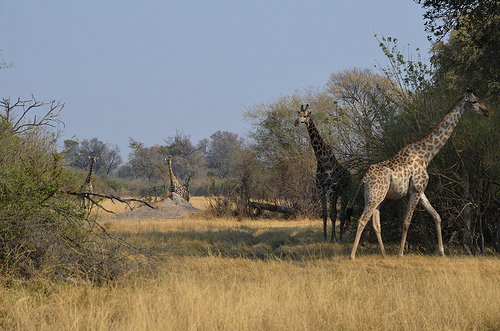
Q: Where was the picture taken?
A: It was taken at the forest.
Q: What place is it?
A: It is a forest.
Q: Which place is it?
A: It is a forest.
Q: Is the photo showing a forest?
A: Yes, it is showing a forest.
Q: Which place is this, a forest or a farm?
A: It is a forest.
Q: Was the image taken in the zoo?
A: No, the picture was taken in the forest.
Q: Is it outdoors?
A: Yes, it is outdoors.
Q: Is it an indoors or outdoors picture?
A: It is outdoors.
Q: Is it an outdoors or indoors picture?
A: It is outdoors.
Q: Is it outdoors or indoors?
A: It is outdoors.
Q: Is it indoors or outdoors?
A: It is outdoors.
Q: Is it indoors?
A: No, it is outdoors.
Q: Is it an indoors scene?
A: No, it is outdoors.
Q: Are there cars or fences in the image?
A: No, there are no fences or cars.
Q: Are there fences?
A: No, there are no fences.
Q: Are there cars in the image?
A: No, there are no cars.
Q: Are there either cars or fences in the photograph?
A: No, there are no cars or fences.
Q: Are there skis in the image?
A: No, there are no skis.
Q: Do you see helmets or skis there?
A: No, there are no skis or helmets.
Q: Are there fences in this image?
A: No, there are no fences.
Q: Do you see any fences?
A: No, there are no fences.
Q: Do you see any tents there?
A: No, there are no tents.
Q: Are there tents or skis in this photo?
A: No, there are no tents or skis.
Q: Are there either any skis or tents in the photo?
A: No, there are no tents or skis.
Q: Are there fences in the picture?
A: No, there are no fences.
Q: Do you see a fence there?
A: No, there are no fences.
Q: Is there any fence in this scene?
A: No, there are no fences.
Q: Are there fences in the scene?
A: No, there are no fences.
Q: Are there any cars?
A: No, there are no cars.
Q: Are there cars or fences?
A: No, there are no cars or fences.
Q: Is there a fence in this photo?
A: No, there are no fences.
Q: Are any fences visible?
A: No, there are no fences.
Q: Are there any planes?
A: No, there are no planes.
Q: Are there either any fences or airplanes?
A: No, there are no airplanes or fences.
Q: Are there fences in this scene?
A: No, there are no fences.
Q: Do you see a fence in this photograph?
A: No, there are no fences.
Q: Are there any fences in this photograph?
A: No, there are no fences.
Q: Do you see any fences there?
A: No, there are no fences.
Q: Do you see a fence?
A: No, there are no fences.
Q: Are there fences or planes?
A: No, there are no fences or planes.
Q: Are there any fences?
A: No, there are no fences.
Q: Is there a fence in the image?
A: No, there are no fences.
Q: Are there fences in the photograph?
A: No, there are no fences.